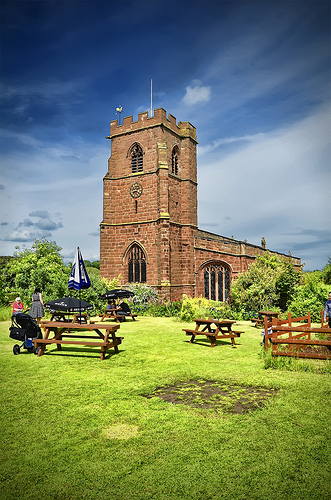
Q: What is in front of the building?
A: Picnic tables.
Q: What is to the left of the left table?
A: Stroller.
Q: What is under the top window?
A: Clock.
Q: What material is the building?
A: Brick.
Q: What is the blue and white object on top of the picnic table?
A: Umbrella.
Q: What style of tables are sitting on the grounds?
A: Picnic.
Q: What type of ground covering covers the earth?
A: Grass.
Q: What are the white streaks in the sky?
A: Clouds.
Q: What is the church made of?
A: Brick.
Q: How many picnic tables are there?
A: Five.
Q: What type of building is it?
A: A church.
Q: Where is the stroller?
A: Left of the table.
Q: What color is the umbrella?
A: White and blue.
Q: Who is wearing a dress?
A: The woman.